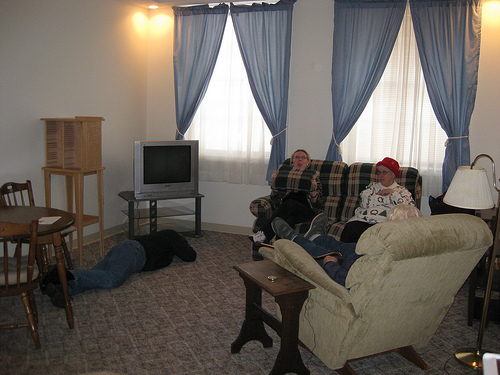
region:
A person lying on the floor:
[40, 225, 200, 310]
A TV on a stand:
[120, 138, 205, 239]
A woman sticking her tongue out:
[290, 147, 309, 170]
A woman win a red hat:
[373, 155, 400, 185]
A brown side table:
[229, 256, 318, 373]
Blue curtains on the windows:
[169, 0, 486, 197]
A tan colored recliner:
[256, 211, 495, 373]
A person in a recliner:
[269, 204, 424, 290]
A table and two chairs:
[0, 179, 79, 351]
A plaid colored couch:
[248, 157, 423, 260]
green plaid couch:
[248, 165, 423, 242]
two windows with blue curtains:
[176, 4, 473, 200]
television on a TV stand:
[124, 138, 205, 233]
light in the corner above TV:
[134, 11, 171, 39]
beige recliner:
[267, 220, 486, 367]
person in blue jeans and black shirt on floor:
[51, 230, 198, 302]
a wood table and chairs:
[1, 186, 75, 348]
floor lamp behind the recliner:
[446, 152, 496, 368]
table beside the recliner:
[230, 261, 307, 373]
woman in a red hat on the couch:
[341, 158, 413, 245]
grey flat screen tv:
[133, 140, 197, 198]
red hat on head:
[375, 158, 401, 178]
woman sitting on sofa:
[270, 149, 320, 231]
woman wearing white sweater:
[347, 156, 415, 246]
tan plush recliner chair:
[261, 212, 495, 374]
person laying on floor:
[42, 228, 199, 292]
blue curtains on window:
[172, 3, 291, 181]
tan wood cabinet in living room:
[36, 115, 103, 245]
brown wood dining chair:
[1, 219, 41, 347]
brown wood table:
[230, 258, 315, 373]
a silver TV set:
[132, 138, 199, 195]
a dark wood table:
[0, 203, 77, 330]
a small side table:
[230, 262, 312, 374]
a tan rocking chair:
[260, 212, 494, 374]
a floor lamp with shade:
[441, 153, 498, 371]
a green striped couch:
[249, 157, 421, 276]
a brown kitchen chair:
[0, 218, 42, 349]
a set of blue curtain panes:
[172, 3, 291, 187]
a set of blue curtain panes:
[331, 0, 480, 195]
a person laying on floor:
[40, 227, 197, 307]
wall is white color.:
[11, 25, 101, 92]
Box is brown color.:
[33, 103, 108, 175]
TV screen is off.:
[126, 134, 235, 231]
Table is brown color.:
[3, 178, 94, 308]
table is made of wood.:
[7, 173, 117, 318]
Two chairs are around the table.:
[6, 171, 77, 328]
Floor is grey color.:
[101, 280, 207, 366]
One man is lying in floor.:
[100, 223, 198, 309]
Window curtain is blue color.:
[156, 15, 317, 125]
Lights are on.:
[121, 5, 497, 42]